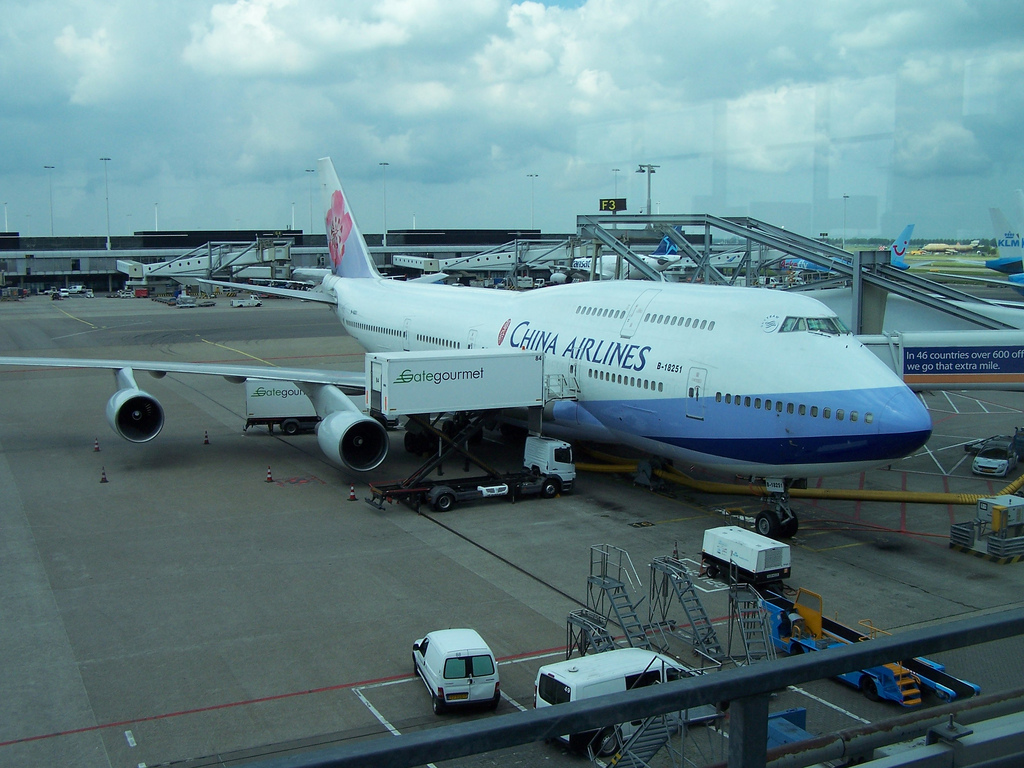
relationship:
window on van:
[579, 352, 665, 398] [413, 629, 501, 716]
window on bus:
[755, 397, 761, 409] [505, 644, 698, 707]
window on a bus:
[740, 381, 795, 429] [527, 640, 716, 742]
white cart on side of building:
[364, 346, 547, 417] [628, 628, 994, 728]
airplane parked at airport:
[171, 127, 1022, 514] [9, 211, 1016, 760]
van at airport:
[397, 607, 506, 702] [5, 158, 1021, 755]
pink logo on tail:
[325, 189, 355, 269] [303, 151, 392, 294]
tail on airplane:
[303, 151, 392, 294] [0, 157, 1022, 493]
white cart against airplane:
[359, 333, 550, 423] [1, 151, 1015, 558]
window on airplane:
[803, 398, 832, 428] [0, 157, 1022, 493]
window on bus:
[675, 379, 737, 418] [7, 153, 990, 512]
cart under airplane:
[293, 425, 549, 508] [56, 105, 960, 522]